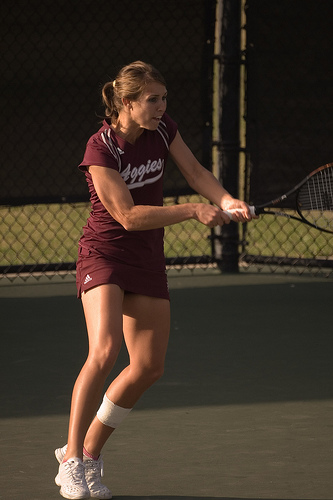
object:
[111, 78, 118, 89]
tie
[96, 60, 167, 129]
hair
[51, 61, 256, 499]
woman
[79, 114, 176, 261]
jersey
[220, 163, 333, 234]
tennis racket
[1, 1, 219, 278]
fence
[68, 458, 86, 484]
laces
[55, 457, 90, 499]
shoe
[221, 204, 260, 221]
handle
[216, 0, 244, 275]
pole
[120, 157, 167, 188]
lettering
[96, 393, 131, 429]
bandage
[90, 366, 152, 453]
calf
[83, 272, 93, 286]
logo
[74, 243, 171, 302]
skirt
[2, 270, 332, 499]
ground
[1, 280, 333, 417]
shadow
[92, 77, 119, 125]
ponytail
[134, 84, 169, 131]
face